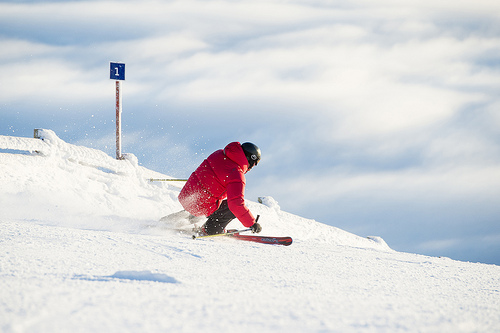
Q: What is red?
A: Jacket.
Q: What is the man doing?
A: Skiing.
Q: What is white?
A: Snow.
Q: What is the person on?
A: Snow.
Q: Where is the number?
A: Post.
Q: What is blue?
A: Sign.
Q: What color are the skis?
A: Red.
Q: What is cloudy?
A: Sky.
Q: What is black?
A: Helmet.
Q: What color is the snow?
A: White.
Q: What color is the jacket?
A: Red.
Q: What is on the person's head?
A: A helmet.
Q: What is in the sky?
A: Clouds.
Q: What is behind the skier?
A: Ski poles.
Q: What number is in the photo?
A: One.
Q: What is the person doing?
A: Skiing.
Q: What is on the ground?
A: Snow.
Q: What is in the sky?
A: Clouds.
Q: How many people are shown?
A: 1.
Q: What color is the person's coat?
A: Red.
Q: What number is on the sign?
A: 1.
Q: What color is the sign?
A: Blue.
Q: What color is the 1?
A: White.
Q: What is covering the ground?
A: Snow.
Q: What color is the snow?
A: White.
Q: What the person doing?
A: Skiing.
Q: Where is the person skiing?
A: On a mountain.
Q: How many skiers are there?
A: 1.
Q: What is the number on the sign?
A: 1.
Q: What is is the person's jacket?
A: Red.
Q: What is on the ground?
A: Snow.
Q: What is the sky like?
A: Cloudy.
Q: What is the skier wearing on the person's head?
A: Helmet.